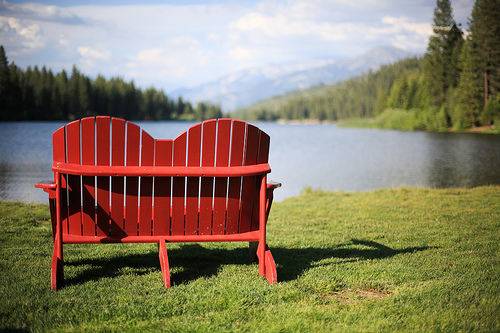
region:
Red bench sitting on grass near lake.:
[34, 111, 285, 301]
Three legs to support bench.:
[43, 233, 289, 292]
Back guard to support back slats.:
[53, 161, 266, 242]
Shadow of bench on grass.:
[282, 232, 447, 292]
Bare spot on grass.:
[318, 273, 412, 309]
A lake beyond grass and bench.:
[283, 125, 498, 187]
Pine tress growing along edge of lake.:
[4, 47, 187, 124]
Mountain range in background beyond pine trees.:
[163, 39, 421, 119]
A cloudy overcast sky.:
[61, 0, 406, 75]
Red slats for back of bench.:
[65, 184, 253, 232]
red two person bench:
[35, 112, 311, 282]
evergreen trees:
[426, 0, 491, 110]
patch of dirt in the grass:
[320, 275, 430, 310]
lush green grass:
[1, 205, 483, 321]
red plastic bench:
[25, 105, 315, 305]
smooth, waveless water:
[0, 110, 495, 211]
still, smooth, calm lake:
[0, 105, 495, 220]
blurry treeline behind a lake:
[0, 42, 425, 117]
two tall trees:
[425, 0, 498, 125]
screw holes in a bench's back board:
[100, 155, 221, 199]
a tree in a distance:
[35, 65, 48, 112]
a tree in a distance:
[49, 67, 71, 117]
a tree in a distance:
[76, 69, 98, 116]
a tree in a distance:
[0, 41, 7, 114]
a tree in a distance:
[139, 85, 158, 119]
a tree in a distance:
[173, 91, 188, 111]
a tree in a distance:
[196, 100, 214, 120]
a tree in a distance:
[146, 88, 167, 124]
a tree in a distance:
[360, 63, 388, 119]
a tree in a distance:
[318, 84, 335, 117]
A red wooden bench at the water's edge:
[37, 107, 281, 287]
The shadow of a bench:
[112, 226, 420, 284]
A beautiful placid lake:
[2, 88, 489, 199]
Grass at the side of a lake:
[301, 201, 483, 310]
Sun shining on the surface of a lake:
[274, 129, 354, 175]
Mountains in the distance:
[240, 34, 436, 107]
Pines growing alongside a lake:
[20, 57, 163, 119]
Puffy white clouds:
[5, 5, 73, 42]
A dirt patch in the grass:
[309, 275, 410, 314]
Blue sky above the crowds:
[41, 0, 98, 8]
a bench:
[37, 114, 293, 293]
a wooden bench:
[34, 113, 297, 286]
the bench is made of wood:
[33, 110, 294, 292]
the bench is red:
[33, 117, 296, 284]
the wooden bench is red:
[37, 115, 292, 291]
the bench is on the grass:
[25, 70, 295, 290]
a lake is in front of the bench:
[5, 67, 497, 212]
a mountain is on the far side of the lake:
[168, 44, 426, 112]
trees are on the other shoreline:
[8, 6, 499, 129]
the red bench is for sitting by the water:
[40, 113, 291, 288]